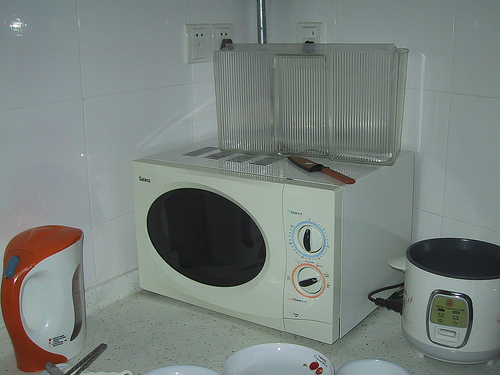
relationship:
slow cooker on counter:
[402, 237, 499, 366] [0, 291, 498, 373]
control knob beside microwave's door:
[286, 217, 330, 261] [129, 157, 343, 345]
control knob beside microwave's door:
[286, 259, 332, 299] [129, 157, 343, 345]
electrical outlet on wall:
[183, 23, 212, 65] [0, 0, 499, 328]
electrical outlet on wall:
[213, 19, 237, 62] [0, 0, 499, 328]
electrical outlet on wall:
[297, 23, 324, 61] [0, 0, 499, 328]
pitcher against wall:
[2, 225, 88, 372] [0, 0, 499, 328]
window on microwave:
[145, 184, 268, 287] [129, 134, 415, 345]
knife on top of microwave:
[285, 152, 355, 186] [129, 134, 415, 345]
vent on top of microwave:
[177, 138, 220, 158] [129, 134, 415, 345]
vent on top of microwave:
[203, 146, 237, 159] [129, 134, 415, 345]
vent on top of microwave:
[226, 149, 260, 163] [129, 134, 415, 345]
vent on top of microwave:
[249, 147, 287, 165] [129, 134, 415, 345]